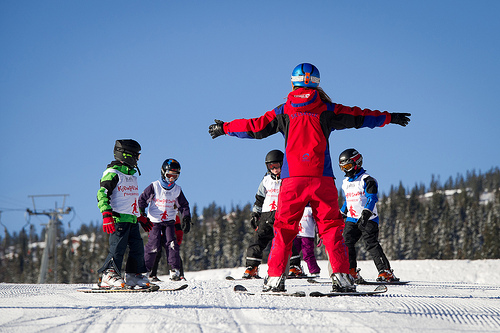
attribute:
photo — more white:
[8, 8, 499, 331]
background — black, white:
[12, 12, 499, 330]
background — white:
[6, 10, 496, 264]